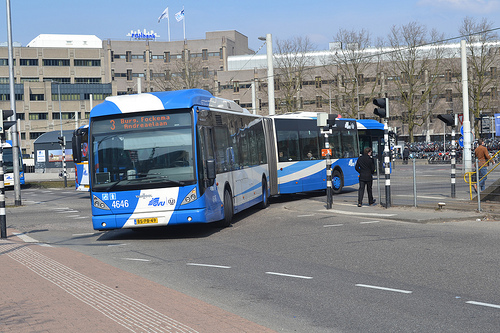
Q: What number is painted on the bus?
A: 4646.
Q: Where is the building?
A: Behind bus.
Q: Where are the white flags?
A: Top of building.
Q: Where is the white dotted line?
A: On road.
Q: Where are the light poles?
A: On sidewalk.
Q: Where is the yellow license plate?
A: Font of bus.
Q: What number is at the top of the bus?
A: 3.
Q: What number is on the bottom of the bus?
A: 4646.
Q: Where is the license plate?
A: On the bumper.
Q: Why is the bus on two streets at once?
A: Two sections.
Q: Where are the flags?
A: Top of building.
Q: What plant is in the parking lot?
A: Tree.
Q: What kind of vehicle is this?
A: Bus.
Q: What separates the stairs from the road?
A: Fence.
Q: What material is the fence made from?
A: Chain link.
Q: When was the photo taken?
A: Daytime.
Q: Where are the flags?
A: Top of the building.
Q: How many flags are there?
A: Two.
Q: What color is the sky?
A: Blue.